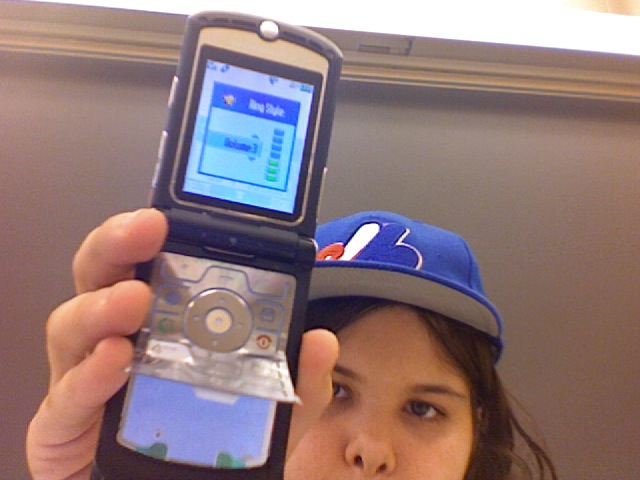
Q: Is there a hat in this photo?
A: Yes, there is a hat.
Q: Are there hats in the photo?
A: Yes, there is a hat.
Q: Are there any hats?
A: Yes, there is a hat.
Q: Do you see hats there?
A: Yes, there is a hat.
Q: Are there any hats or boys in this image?
A: Yes, there is a hat.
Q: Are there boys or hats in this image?
A: Yes, there is a hat.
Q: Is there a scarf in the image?
A: No, there are no scarves.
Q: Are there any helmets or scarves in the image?
A: No, there are no scarves or helmets.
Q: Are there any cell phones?
A: Yes, there is a cell phone.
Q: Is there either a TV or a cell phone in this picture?
A: Yes, there is a cell phone.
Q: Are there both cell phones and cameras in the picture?
A: No, there is a cell phone but no cameras.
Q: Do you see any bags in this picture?
A: No, there are no bags.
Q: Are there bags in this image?
A: No, there are no bags.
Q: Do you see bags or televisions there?
A: No, there are no bags or televisions.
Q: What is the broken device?
A: The device is a cell phone.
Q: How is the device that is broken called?
A: The device is a cell phone.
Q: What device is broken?
A: The device is a cell phone.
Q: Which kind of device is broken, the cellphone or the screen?
A: The cellphone is broken.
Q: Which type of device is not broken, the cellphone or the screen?
A: The screen is not broken.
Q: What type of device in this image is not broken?
A: The device is a screen.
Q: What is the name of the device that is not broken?
A: The device is a screen.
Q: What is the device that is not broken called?
A: The device is a screen.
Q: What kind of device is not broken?
A: The device is a screen.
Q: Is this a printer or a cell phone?
A: This is a cell phone.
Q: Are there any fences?
A: No, there are no fences.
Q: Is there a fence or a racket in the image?
A: No, there are no fences or rackets.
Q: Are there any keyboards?
A: Yes, there is a keyboard.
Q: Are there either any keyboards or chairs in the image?
A: Yes, there is a keyboard.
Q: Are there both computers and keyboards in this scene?
A: No, there is a keyboard but no computers.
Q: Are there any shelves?
A: No, there are no shelves.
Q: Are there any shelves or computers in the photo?
A: No, there are no shelves or computers.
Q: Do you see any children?
A: Yes, there is a child.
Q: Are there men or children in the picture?
A: Yes, there is a child.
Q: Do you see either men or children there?
A: Yes, there is a child.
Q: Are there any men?
A: No, there are no men.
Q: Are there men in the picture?
A: No, there are no men.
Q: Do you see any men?
A: No, there are no men.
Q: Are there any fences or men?
A: No, there are no men or fences.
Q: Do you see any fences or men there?
A: No, there are no men or fences.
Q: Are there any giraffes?
A: No, there are no giraffes.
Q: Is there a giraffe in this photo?
A: No, there are no giraffes.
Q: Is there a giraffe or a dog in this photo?
A: No, there are no giraffes or dogs.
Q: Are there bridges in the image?
A: Yes, there is a bridge.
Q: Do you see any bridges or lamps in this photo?
A: Yes, there is a bridge.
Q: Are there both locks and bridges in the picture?
A: No, there is a bridge but no locks.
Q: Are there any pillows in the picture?
A: No, there are no pillows.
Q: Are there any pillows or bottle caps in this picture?
A: No, there are no pillows or bottle caps.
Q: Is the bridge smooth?
A: Yes, the bridge is smooth.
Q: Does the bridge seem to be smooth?
A: Yes, the bridge is smooth.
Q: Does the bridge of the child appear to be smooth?
A: Yes, the bridge is smooth.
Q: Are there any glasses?
A: No, there are no glasses.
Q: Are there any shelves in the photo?
A: No, there are no shelves.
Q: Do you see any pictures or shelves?
A: No, there are no shelves or pictures.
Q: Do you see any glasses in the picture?
A: No, there are no glasses.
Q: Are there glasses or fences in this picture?
A: No, there are no glasses or fences.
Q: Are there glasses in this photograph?
A: No, there are no glasses.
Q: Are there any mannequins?
A: No, there are no mannequins.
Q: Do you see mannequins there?
A: No, there are no mannequins.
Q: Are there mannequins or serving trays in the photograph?
A: No, there are no mannequins or serving trays.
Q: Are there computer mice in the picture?
A: No, there are no computer mice.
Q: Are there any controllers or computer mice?
A: No, there are no computer mice or controllers.